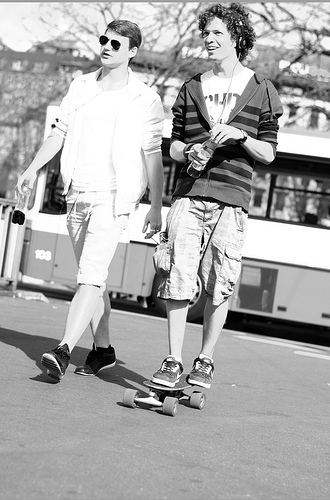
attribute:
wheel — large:
[187, 387, 208, 410]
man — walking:
[15, 21, 167, 381]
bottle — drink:
[178, 131, 220, 186]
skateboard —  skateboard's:
[119, 362, 218, 428]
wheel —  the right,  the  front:
[156, 394, 180, 413]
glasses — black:
[89, 33, 141, 67]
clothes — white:
[48, 65, 167, 295]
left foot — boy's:
[85, 340, 118, 373]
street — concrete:
[6, 297, 318, 490]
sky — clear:
[3, 3, 51, 44]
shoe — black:
[36, 327, 87, 388]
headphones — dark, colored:
[238, 35, 249, 53]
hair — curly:
[225, 5, 253, 36]